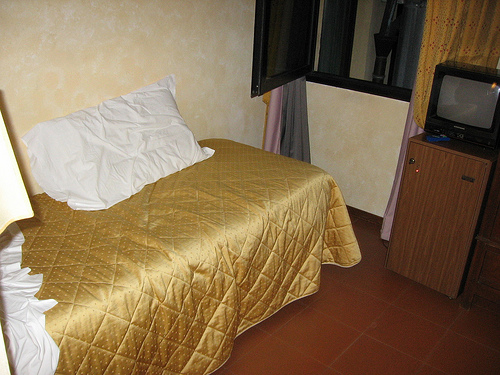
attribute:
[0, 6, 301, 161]
wall — yellow , white.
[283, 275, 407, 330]
floor — tiled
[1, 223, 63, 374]
sheets — white.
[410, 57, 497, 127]
television — black , small.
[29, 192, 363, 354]
quilt — gold , patch 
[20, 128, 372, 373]
quilt —  gold , patch , gold 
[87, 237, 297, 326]
gold quilt — patch , gold 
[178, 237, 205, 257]
patch — gold 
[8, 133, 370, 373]
bedspread — gold 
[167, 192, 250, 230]
quilt — patch ,  gold 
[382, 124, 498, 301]
refrigerator — top 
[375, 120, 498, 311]
refrigerator — small 